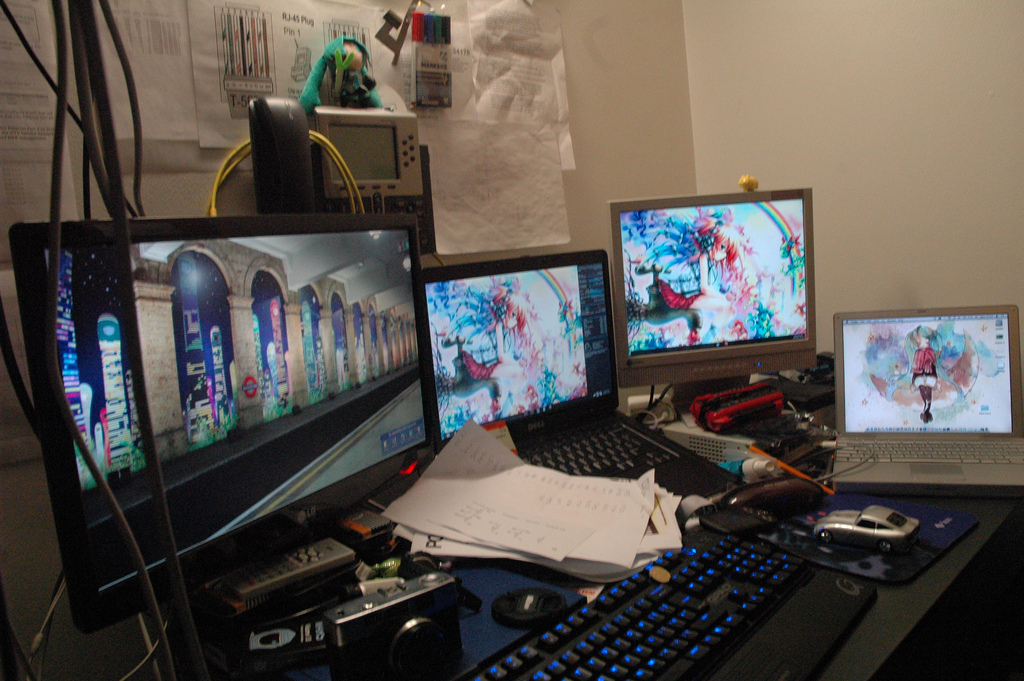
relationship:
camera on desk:
[325, 567, 464, 676] [75, 353, 1018, 676]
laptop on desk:
[829, 303, 1020, 491] [75, 353, 1018, 676]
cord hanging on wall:
[195, 122, 368, 216] [20, 26, 993, 582]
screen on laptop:
[415, 253, 610, 424] [410, 229, 745, 519]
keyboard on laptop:
[514, 418, 679, 481] [415, 244, 740, 506]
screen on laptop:
[424, 263, 611, 441] [432, 229, 735, 506]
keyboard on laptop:
[497, 395, 688, 482] [402, 201, 740, 564]